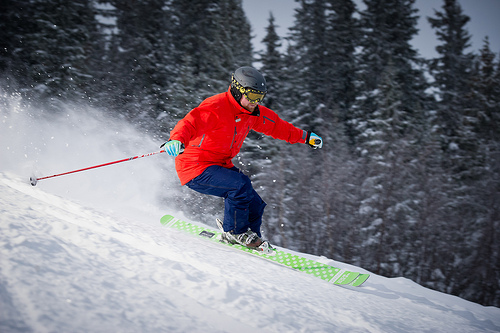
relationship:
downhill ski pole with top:
[28, 140, 182, 186] [137, 136, 161, 157]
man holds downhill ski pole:
[156, 55, 327, 251] [28, 140, 182, 186]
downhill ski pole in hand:
[28, 140, 182, 186] [160, 135, 190, 160]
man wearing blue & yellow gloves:
[156, 55, 327, 251] [162, 138, 179, 155]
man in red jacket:
[156, 55, 327, 251] [161, 85, 308, 189]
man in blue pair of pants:
[156, 55, 327, 251] [185, 161, 264, 235]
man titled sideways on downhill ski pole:
[156, 55, 327, 251] [28, 140, 182, 186]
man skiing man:
[156, 55, 327, 251] [161, 65, 322, 251]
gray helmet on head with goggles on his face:
[230, 63, 266, 102] [228, 76, 268, 104]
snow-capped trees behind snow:
[5, 0, 497, 293] [16, 207, 475, 326]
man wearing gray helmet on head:
[161, 65, 322, 251] [230, 63, 266, 102]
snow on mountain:
[33, 202, 158, 303] [2, 156, 457, 328]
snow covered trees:
[334, 165, 396, 243] [312, 15, 453, 270]